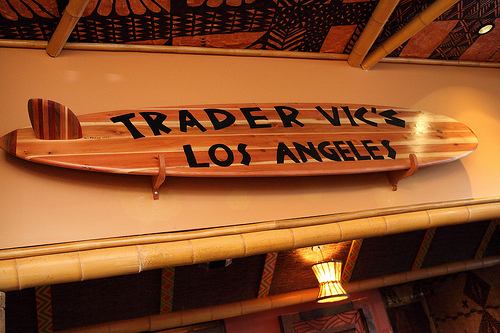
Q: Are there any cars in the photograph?
A: No, there are no cars.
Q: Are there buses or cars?
A: No, there are no cars or buses.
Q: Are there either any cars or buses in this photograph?
A: No, there are no cars or buses.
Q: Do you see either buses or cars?
A: No, there are no cars or buses.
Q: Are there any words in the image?
A: Yes, there are words.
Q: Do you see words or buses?
A: Yes, there are words.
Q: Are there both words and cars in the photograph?
A: No, there are words but no cars.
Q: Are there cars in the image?
A: No, there are no cars.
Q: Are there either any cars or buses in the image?
A: No, there are no cars or buses.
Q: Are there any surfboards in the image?
A: Yes, there is a surfboard.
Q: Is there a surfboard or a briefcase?
A: Yes, there is a surfboard.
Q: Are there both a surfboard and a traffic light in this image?
A: No, there is a surfboard but no traffic lights.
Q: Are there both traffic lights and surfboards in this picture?
A: No, there is a surfboard but no traffic lights.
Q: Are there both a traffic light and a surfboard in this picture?
A: No, there is a surfboard but no traffic lights.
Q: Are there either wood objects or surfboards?
A: Yes, there is a wood surfboard.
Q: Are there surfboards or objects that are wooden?
A: Yes, the surfboard is wooden.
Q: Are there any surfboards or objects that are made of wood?
A: Yes, the surfboard is made of wood.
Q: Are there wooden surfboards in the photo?
A: Yes, there is a wood surfboard.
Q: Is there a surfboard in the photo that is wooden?
A: Yes, there is a surfboard that is wooden.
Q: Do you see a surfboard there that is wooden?
A: Yes, there is a surfboard that is wooden.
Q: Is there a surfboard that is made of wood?
A: Yes, there is a surfboard that is made of wood.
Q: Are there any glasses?
A: No, there are no glasses.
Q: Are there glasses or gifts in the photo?
A: No, there are no glasses or gifts.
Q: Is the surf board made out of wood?
A: Yes, the surf board is made of wood.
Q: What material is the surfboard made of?
A: The surfboard is made of wood.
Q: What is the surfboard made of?
A: The surfboard is made of wood.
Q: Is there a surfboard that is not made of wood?
A: No, there is a surfboard but it is made of wood.